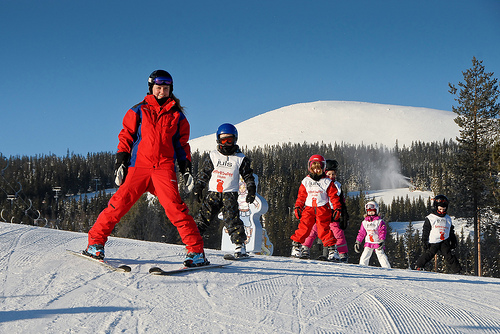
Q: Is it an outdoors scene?
A: Yes, it is outdoors.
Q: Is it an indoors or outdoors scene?
A: It is outdoors.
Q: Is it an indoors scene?
A: No, it is outdoors.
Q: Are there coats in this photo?
A: Yes, there is a coat.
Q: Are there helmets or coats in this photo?
A: Yes, there is a coat.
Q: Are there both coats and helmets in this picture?
A: Yes, there are both a coat and a helmet.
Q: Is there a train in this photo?
A: No, there are no trains.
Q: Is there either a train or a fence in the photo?
A: No, there are no trains or fences.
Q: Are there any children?
A: Yes, there is a child.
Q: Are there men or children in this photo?
A: Yes, there is a child.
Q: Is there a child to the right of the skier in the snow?
A: Yes, there is a child to the right of the skier.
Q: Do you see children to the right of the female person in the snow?
A: Yes, there is a child to the right of the skier.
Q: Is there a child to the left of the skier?
A: No, the child is to the right of the skier.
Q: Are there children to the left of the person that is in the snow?
A: No, the child is to the right of the skier.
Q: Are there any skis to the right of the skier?
A: No, there is a child to the right of the skier.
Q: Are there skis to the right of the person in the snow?
A: No, there is a child to the right of the skier.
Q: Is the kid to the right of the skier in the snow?
A: Yes, the kid is to the right of the skier.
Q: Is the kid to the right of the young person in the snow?
A: Yes, the kid is to the right of the skier.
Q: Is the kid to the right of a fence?
A: No, the kid is to the right of the skier.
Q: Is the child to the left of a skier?
A: No, the child is to the right of a skier.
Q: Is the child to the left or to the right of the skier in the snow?
A: The child is to the right of the skier.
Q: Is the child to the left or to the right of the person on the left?
A: The child is to the right of the skier.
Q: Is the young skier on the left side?
A: Yes, the skier is on the left of the image.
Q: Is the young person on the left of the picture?
A: Yes, the skier is on the left of the image.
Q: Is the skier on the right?
A: No, the skier is on the left of the image.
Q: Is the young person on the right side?
A: No, the skier is on the left of the image.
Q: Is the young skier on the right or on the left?
A: The skier is on the left of the image.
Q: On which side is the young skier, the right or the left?
A: The skier is on the left of the image.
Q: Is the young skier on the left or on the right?
A: The skier is on the left of the image.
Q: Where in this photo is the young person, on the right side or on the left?
A: The skier is on the left of the image.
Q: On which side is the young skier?
A: The skier is on the left of the image.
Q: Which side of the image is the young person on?
A: The skier is on the left of the image.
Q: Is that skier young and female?
A: Yes, the skier is young and female.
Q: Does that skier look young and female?
A: Yes, the skier is young and female.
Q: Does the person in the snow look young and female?
A: Yes, the skier is young and female.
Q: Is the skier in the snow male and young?
A: No, the skier is young but female.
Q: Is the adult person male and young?
A: No, the skier is young but female.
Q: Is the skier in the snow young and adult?
A: Yes, the skier is young and adult.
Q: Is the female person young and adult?
A: Yes, the skier is young and adult.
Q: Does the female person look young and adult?
A: Yes, the skier is young and adult.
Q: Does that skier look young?
A: Yes, the skier is young.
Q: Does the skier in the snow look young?
A: Yes, the skier is young.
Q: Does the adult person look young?
A: Yes, the skier is young.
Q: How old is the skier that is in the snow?
A: The skier is young.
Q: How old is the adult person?
A: The skier is young.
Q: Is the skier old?
A: No, the skier is young.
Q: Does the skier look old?
A: No, the skier is young.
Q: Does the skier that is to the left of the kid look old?
A: No, the skier is young.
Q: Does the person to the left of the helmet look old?
A: No, the skier is young.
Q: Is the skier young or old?
A: The skier is young.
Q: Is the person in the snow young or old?
A: The skier is young.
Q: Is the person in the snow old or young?
A: The skier is young.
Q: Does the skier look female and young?
A: Yes, the skier is female and young.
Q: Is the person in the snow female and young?
A: Yes, the skier is female and young.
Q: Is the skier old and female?
A: No, the skier is female but young.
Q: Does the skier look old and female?
A: No, the skier is female but young.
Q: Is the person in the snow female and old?
A: No, the skier is female but young.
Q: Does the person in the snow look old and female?
A: No, the skier is female but young.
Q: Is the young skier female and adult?
A: Yes, the skier is female and adult.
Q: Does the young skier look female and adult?
A: Yes, the skier is female and adult.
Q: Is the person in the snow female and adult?
A: Yes, the skier is female and adult.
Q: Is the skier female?
A: Yes, the skier is female.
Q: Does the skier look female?
A: Yes, the skier is female.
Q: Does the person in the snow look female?
A: Yes, the skier is female.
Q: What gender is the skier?
A: The skier is female.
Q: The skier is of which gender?
A: The skier is female.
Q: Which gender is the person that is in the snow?
A: The skier is female.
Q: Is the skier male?
A: No, the skier is female.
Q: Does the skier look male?
A: No, the skier is female.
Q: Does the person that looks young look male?
A: No, the skier is female.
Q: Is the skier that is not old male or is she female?
A: The skier is female.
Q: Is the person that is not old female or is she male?
A: The skier is female.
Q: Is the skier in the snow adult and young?
A: Yes, the skier is adult and young.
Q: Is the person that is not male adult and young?
A: Yes, the skier is adult and young.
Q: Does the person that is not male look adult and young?
A: Yes, the skier is adult and young.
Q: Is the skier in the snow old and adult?
A: No, the skier is adult but young.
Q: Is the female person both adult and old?
A: No, the skier is adult but young.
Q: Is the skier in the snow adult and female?
A: Yes, the skier is adult and female.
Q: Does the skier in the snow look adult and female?
A: Yes, the skier is adult and female.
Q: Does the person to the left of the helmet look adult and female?
A: Yes, the skier is adult and female.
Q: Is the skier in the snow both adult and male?
A: No, the skier is adult but female.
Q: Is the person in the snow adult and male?
A: No, the skier is adult but female.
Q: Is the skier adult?
A: Yes, the skier is adult.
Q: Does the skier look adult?
A: Yes, the skier is adult.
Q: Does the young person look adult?
A: Yes, the skier is adult.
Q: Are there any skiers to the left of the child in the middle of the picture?
A: Yes, there is a skier to the left of the child.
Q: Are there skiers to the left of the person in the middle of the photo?
A: Yes, there is a skier to the left of the child.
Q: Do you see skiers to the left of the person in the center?
A: Yes, there is a skier to the left of the child.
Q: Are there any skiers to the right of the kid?
A: No, the skier is to the left of the kid.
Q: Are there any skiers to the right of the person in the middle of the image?
A: No, the skier is to the left of the kid.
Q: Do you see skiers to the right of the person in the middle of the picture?
A: No, the skier is to the left of the kid.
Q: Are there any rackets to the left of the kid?
A: No, there is a skier to the left of the kid.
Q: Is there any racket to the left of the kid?
A: No, there is a skier to the left of the kid.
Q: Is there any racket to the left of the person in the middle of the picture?
A: No, there is a skier to the left of the kid.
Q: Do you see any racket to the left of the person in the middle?
A: No, there is a skier to the left of the kid.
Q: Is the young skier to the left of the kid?
A: Yes, the skier is to the left of the kid.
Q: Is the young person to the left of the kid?
A: Yes, the skier is to the left of the kid.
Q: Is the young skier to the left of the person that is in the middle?
A: Yes, the skier is to the left of the kid.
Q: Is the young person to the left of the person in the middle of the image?
A: Yes, the skier is to the left of the kid.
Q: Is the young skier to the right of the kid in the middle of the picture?
A: No, the skier is to the left of the kid.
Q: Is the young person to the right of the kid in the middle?
A: No, the skier is to the left of the kid.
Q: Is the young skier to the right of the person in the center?
A: No, the skier is to the left of the kid.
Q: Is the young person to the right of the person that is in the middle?
A: No, the skier is to the left of the kid.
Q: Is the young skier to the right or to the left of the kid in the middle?
A: The skier is to the left of the child.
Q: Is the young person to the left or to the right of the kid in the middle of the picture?
A: The skier is to the left of the child.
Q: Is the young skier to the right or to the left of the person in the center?
A: The skier is to the left of the child.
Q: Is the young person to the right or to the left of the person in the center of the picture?
A: The skier is to the left of the child.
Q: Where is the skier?
A: The skier is in the snow.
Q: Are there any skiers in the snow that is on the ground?
A: Yes, there is a skier in the snow.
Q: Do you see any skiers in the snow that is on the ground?
A: Yes, there is a skier in the snow.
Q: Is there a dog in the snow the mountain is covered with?
A: No, there is a skier in the snow.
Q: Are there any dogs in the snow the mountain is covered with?
A: No, there is a skier in the snow.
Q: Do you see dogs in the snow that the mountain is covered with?
A: No, there is a skier in the snow.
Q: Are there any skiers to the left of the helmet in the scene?
A: Yes, there is a skier to the left of the helmet.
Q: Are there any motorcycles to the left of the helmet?
A: No, there is a skier to the left of the helmet.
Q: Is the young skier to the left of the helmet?
A: Yes, the skier is to the left of the helmet.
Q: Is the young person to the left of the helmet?
A: Yes, the skier is to the left of the helmet.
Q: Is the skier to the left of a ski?
A: No, the skier is to the left of the helmet.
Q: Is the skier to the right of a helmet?
A: No, the skier is to the left of a helmet.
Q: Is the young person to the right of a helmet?
A: No, the skier is to the left of a helmet.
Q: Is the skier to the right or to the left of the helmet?
A: The skier is to the left of the helmet.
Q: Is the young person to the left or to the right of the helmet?
A: The skier is to the left of the helmet.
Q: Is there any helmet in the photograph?
A: Yes, there is a helmet.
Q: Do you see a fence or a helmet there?
A: Yes, there is a helmet.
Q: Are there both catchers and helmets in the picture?
A: No, there is a helmet but no catchers.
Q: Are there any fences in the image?
A: No, there are no fences.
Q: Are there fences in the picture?
A: No, there are no fences.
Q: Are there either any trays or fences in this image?
A: No, there are no fences or trays.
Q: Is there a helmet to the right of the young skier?
A: Yes, there is a helmet to the right of the skier.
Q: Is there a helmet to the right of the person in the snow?
A: Yes, there is a helmet to the right of the skier.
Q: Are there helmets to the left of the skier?
A: No, the helmet is to the right of the skier.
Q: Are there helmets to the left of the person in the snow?
A: No, the helmet is to the right of the skier.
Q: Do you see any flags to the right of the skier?
A: No, there is a helmet to the right of the skier.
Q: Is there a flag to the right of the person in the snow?
A: No, there is a helmet to the right of the skier.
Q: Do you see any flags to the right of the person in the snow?
A: No, there is a helmet to the right of the skier.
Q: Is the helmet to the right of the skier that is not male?
A: Yes, the helmet is to the right of the skier.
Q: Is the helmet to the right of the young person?
A: Yes, the helmet is to the right of the skier.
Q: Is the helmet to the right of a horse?
A: No, the helmet is to the right of the skier.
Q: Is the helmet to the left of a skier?
A: No, the helmet is to the right of a skier.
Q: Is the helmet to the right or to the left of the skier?
A: The helmet is to the right of the skier.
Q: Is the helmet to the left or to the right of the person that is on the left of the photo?
A: The helmet is to the right of the skier.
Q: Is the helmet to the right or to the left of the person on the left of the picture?
A: The helmet is to the right of the skier.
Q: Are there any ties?
A: No, there are no ties.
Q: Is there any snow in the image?
A: Yes, there is snow.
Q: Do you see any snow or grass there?
A: Yes, there is snow.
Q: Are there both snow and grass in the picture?
A: No, there is snow but no grass.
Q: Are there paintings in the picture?
A: No, there are no paintings.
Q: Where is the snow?
A: The snow is on the ground.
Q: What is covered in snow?
A: The mountain is covered in snow.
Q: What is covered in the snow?
A: The mountain is covered in snow.